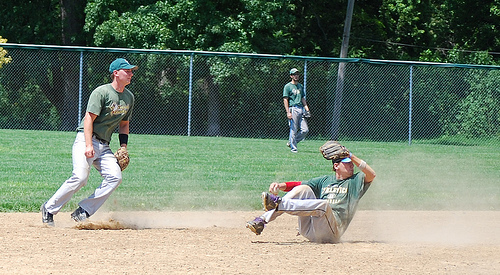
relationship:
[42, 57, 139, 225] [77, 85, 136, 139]
man in t shirt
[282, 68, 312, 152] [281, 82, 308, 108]
man in shirt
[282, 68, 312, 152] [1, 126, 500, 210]
man standing in grass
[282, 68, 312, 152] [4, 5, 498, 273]
man playing baseball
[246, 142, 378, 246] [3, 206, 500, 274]
man sliding on ground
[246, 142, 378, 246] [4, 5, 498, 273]
man playing baseball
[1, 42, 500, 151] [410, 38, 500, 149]
fence in front of bush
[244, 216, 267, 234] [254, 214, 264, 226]
cleats with laces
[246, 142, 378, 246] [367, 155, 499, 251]
player surrounded by dust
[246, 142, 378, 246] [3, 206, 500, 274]
ballplayer on ground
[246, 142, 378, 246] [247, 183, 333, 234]
ballplayer with legs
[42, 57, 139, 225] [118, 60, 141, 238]
man leaning forward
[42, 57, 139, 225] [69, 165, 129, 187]
man with knees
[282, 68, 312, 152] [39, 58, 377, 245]
player watching action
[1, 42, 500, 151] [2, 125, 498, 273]
fence around baseball field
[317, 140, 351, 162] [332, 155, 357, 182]
glove above head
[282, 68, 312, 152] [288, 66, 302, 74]
player wearing cap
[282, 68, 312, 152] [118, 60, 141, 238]
player looking forward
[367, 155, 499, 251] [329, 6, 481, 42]
dust kicked up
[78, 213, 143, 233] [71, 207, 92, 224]
dust in front of shoe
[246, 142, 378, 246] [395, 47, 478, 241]
man looking same direction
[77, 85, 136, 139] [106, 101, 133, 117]
shirt with writing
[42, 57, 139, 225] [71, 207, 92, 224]
man has shoe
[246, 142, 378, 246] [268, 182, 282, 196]
player preparing to throw ball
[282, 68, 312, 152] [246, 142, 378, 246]
player observing man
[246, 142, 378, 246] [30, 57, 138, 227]
man making stop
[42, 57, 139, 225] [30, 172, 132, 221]
man sliding to a stop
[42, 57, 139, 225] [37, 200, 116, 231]
man stop on feet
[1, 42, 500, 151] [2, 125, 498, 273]
fence denoting end of baseball field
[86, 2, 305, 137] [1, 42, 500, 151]
tree behind fence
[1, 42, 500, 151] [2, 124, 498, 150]
fence at edge of outfield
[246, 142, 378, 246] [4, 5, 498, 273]
player holding baseball